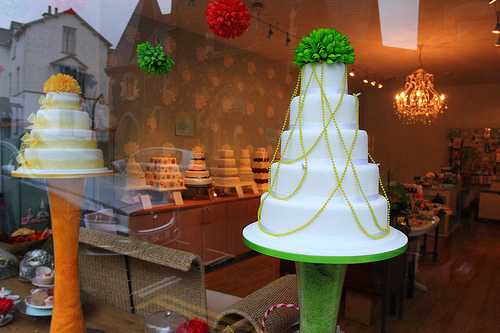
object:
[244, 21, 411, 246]
cake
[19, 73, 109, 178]
cake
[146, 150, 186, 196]
cake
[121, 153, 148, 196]
cake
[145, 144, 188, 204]
cakes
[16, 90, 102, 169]
cake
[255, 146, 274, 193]
cake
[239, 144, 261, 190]
cake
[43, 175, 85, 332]
orange pedestal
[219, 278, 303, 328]
arm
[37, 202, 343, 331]
chair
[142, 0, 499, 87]
ceiling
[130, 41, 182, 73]
adornment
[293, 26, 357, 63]
adornment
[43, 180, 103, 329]
base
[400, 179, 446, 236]
treats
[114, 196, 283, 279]
cabinet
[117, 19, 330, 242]
wall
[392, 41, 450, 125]
chandelier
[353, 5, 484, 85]
ceiling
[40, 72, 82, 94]
adornment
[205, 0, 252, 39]
decoration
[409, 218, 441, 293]
table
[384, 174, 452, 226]
objects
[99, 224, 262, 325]
bench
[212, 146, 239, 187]
cake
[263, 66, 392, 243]
beads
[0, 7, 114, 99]
house reflection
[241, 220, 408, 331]
green white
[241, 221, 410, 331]
table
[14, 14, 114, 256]
building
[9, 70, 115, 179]
cake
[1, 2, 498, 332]
bakery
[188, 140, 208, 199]
cake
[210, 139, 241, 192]
cake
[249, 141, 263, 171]
cake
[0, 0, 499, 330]
reflection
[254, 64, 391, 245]
cake